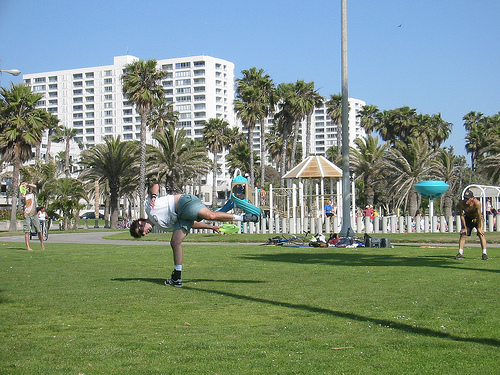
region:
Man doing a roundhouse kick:
[120, 178, 262, 290]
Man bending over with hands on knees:
[452, 185, 484, 257]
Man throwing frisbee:
[12, 180, 48, 251]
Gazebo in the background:
[270, 141, 352, 241]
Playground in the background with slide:
[200, 168, 265, 234]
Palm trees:
[1, 60, 496, 218]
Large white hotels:
[10, 48, 375, 214]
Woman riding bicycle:
[26, 202, 52, 242]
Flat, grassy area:
[5, 215, 498, 370]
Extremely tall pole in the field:
[332, 1, 355, 251]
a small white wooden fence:
[152, 216, 499, 233]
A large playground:
[200, 150, 499, 230]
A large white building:
[19, 45, 236, 212]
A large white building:
[234, 93, 369, 179]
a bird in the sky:
[391, 18, 406, 32]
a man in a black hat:
[450, 186, 489, 261]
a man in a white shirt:
[128, 181, 260, 290]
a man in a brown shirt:
[17, 179, 47, 251]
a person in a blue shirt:
[323, 200, 335, 215]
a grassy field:
[1, 239, 499, 373]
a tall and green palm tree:
[120, 58, 162, 232]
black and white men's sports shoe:
[160, 272, 185, 288]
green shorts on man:
[171, 190, 208, 237]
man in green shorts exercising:
[124, 178, 262, 291]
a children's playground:
[176, 149, 495, 234]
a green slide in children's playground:
[210, 173, 265, 220]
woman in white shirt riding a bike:
[20, 205, 52, 241]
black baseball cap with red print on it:
[461, 188, 475, 202]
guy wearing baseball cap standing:
[450, 189, 490, 264]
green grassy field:
[0, 238, 497, 367]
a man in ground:
[90, 190, 250, 297]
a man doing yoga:
[132, 173, 303, 282]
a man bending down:
[121, 185, 315, 322]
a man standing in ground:
[102, 193, 357, 355]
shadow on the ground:
[231, 283, 423, 370]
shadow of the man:
[220, 290, 421, 372]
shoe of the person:
[158, 254, 202, 300]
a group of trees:
[54, 86, 271, 198]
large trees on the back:
[73, 92, 264, 191]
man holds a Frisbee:
[126, 170, 268, 295]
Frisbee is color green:
[219, 220, 244, 236]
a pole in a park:
[328, 4, 375, 259]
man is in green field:
[446, 185, 493, 277]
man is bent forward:
[445, 183, 491, 268]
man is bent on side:
[126, 173, 260, 285]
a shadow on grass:
[200, 277, 498, 353]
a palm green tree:
[236, 65, 276, 181]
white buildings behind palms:
[12, 47, 375, 189]